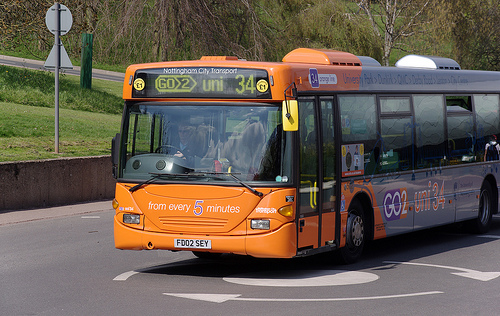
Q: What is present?
A: A bus.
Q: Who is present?
A: Nobody.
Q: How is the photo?
A: Clear.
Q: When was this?
A: Daytime.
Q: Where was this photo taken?
A: Parking lot.